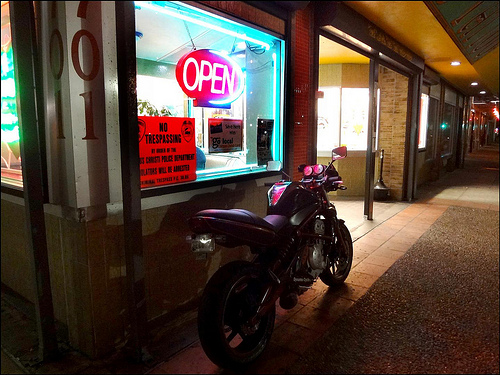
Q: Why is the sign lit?
A: The store is open.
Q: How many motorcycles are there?
A: 1.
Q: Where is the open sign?
A: In the window.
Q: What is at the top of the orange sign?
A: No Trespassing.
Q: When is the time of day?
A: Night.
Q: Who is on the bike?
A: No one.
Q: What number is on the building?
A: 701.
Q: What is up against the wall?
A: Motorcycle.